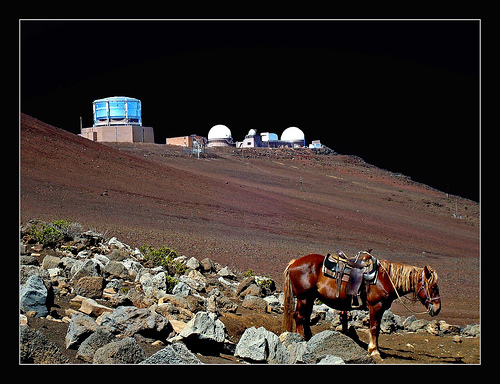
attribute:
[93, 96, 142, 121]
water tower — Bright blue water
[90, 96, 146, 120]
globe — white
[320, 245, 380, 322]
saddle — leather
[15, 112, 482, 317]
slope — brown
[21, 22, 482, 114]
sky — dark, night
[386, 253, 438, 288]
mane — blonde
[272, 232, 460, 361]
horse — brown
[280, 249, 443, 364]
horse — brown 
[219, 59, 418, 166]
sky — dark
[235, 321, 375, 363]
rocks — Large 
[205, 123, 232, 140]
globe — white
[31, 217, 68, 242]
grass — patch 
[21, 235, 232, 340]
rocks — large 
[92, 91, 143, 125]
boiler — blue, large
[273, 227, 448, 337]
horse — brown 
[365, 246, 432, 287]
blonde hair — blonde 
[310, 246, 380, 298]
saddle — leather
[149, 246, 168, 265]
bushes — small, green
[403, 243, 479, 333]
face — HORSE'S 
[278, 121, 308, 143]
globe — white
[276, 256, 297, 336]
hair — blonde  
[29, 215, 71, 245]
plants — Small green